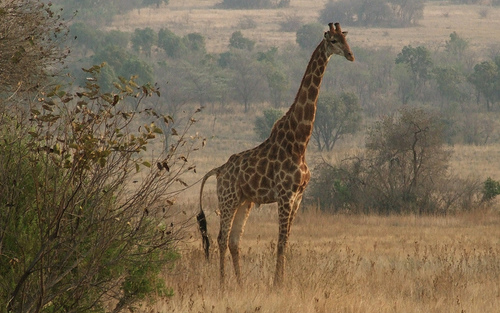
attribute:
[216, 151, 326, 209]
lines — white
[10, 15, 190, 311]
foliage — dry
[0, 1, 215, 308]
bushes — green, brown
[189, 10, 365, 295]
giraffe — still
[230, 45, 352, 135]
neck — stiff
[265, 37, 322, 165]
neck — tall, slender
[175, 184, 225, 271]
tail — part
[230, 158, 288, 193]
spots — brown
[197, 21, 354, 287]
giraffe — brown, tan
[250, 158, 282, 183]
spot — brown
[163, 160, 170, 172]
leaf — brown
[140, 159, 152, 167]
leaf — brown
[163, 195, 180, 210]
leaf — brown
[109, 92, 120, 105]
leaf — brown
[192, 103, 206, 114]
leaf — brown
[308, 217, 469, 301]
plains — dry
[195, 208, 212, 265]
tuft — long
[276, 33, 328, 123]
mane — short